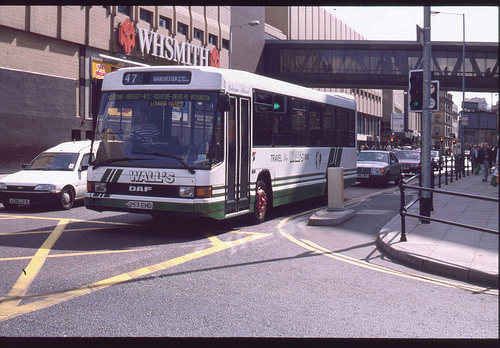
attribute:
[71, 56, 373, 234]
bus — green, white, moving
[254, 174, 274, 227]
bus wheel — black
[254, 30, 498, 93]
bridge — overhead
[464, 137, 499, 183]
people — walking down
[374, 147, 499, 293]
sidewalk — pedestrian restraint, enclosed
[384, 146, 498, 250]
iron gate — black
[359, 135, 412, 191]
car — grey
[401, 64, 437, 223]
street light — green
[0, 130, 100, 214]
car — white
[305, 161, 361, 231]
barrier — concrete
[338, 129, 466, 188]
traffic — heavy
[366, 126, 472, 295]
barrier — black, metal 